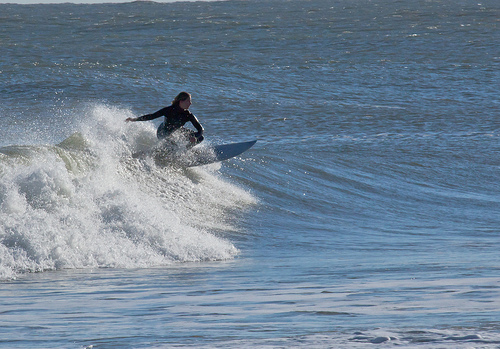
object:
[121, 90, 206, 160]
surfer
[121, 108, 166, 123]
arm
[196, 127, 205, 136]
elbow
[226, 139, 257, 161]
up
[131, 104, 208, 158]
wetsuit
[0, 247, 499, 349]
water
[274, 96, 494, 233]
curve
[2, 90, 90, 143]
drops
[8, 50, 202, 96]
lighter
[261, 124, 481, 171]
line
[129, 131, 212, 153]
riding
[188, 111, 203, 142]
arm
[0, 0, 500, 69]
distance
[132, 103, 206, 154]
wearing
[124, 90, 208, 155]
person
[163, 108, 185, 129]
black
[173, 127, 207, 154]
leg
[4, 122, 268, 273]
wave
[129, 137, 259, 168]
board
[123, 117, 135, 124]
hand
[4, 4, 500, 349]
ocean water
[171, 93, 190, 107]
hair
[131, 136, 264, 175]
surfboard